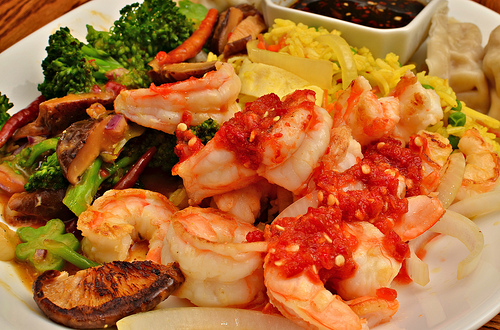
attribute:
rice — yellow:
[242, 16, 497, 154]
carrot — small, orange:
[256, 33, 290, 50]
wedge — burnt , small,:
[34, 255, 179, 328]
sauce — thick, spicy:
[287, 0, 424, 60]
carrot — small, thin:
[151, 4, 222, 74]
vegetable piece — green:
[19, 216, 86, 274]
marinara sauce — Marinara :
[215, 89, 320, 169]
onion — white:
[319, 31, 359, 89]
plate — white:
[0, 1, 498, 327]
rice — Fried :
[282, 19, 454, 108]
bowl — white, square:
[13, 8, 498, 323]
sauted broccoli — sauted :
[36, 0, 195, 101]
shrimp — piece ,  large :
[172, 85, 334, 197]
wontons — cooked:
[424, 0, 494, 108]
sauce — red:
[264, 205, 358, 282]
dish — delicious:
[3, 2, 499, 328]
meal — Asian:
[0, 7, 499, 328]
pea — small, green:
[446, 109, 465, 127]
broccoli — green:
[81, 12, 184, 93]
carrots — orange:
[141, 6, 220, 161]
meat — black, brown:
[30, 257, 177, 308]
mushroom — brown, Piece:
[51, 120, 118, 177]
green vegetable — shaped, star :
[10, 217, 93, 271]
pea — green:
[448, 108, 466, 127]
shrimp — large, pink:
[102, 73, 450, 325]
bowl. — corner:
[266, 4, 447, 62]